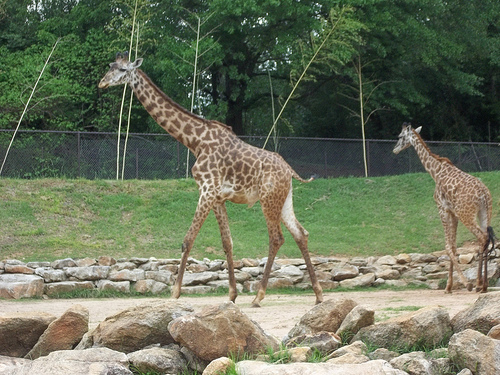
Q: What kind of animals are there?
A: Giraffes.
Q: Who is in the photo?
A: Nobody.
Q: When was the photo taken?
A: Daytime.